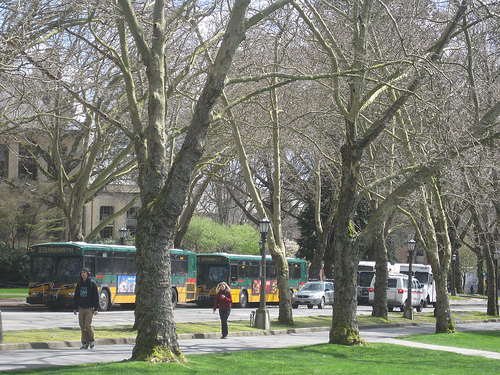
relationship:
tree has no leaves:
[295, 22, 409, 344] [272, 47, 325, 125]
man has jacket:
[67, 265, 99, 345] [76, 279, 98, 309]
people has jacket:
[211, 280, 235, 341] [213, 292, 234, 308]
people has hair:
[211, 280, 235, 341] [213, 279, 235, 292]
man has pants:
[67, 265, 99, 345] [75, 304, 97, 345]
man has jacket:
[67, 265, 99, 345] [72, 278, 100, 311]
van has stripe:
[371, 273, 426, 308] [405, 290, 421, 294]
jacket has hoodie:
[76, 279, 98, 309] [84, 274, 93, 284]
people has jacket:
[211, 280, 235, 341] [212, 290, 233, 312]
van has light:
[371, 273, 426, 308] [397, 288, 404, 297]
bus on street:
[24, 240, 196, 310] [1, 306, 499, 332]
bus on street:
[197, 250, 309, 307] [1, 306, 499, 332]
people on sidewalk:
[66, 262, 243, 366] [36, 325, 329, 366]